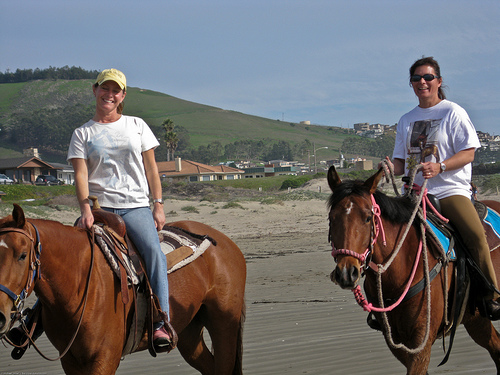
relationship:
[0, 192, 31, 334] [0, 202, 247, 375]
head of horse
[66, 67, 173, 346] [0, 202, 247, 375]
lady on horse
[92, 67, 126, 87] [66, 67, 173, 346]
cap on lady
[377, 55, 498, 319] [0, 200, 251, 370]
women on horses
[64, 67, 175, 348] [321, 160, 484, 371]
women on horses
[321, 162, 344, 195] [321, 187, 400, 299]
ear of horse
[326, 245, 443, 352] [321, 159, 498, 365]
bridle of horse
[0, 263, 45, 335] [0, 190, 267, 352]
bridle of horse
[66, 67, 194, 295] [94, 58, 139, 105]
woman wearing cap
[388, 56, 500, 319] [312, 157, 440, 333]
lady riding horse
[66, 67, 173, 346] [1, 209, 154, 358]
lady riding horse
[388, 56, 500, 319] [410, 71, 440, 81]
lady wearing sunglasses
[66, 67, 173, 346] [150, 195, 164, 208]
lady wearing watch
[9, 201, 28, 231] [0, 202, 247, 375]
ear of horse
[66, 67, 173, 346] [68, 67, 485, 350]
lady on a horse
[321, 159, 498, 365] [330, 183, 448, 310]
horse wearing harness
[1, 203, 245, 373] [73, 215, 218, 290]
brown horse wearing a saddle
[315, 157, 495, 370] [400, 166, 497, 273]
brown horse wearing saddle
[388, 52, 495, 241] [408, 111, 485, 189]
lady wearing tee shirt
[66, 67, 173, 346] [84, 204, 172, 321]
lady wearing jeans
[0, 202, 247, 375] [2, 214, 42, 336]
horse wearing harness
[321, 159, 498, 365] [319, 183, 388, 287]
horse wearing harness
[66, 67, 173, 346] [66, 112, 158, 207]
lady wearing t shirt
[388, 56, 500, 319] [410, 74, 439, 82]
lady wearing glasses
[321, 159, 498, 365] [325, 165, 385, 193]
horse has ear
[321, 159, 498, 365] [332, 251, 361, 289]
horse has nose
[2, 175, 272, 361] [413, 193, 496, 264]
horse has saddle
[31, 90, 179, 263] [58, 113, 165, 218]
lady wearing tee shirt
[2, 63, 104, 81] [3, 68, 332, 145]
trees are a top of hill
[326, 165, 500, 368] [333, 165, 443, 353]
horse has bridle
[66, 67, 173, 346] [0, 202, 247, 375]
lady riding horse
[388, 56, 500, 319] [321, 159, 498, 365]
lady riding horse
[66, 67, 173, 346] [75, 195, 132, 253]
lady wearing sadlle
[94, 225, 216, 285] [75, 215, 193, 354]
blanket on saddle